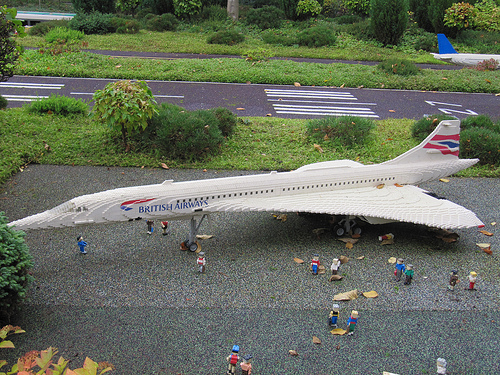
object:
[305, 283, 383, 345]
lego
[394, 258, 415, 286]
spectators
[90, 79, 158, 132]
leaves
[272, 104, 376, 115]
lines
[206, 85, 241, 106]
asphalt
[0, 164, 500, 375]
tarmac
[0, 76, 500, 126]
runway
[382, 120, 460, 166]
tail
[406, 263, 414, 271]
head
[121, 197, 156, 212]
logo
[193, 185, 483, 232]
wing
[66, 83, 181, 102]
line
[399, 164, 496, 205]
windows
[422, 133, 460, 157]
logo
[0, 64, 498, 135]
road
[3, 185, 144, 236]
plane front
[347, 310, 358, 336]
model spectator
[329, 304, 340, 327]
model spectator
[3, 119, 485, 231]
airplane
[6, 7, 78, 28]
building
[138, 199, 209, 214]
british airways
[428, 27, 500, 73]
tail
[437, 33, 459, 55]
tail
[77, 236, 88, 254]
figurine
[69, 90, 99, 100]
white line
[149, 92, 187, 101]
white line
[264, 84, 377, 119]
lines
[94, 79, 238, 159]
bushes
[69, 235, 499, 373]
people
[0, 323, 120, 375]
leaves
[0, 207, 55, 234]
nose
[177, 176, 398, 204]
small windows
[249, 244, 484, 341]
figures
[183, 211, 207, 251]
landing gear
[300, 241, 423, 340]
people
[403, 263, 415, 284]
person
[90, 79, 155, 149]
bush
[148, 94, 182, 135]
bush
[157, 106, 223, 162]
bush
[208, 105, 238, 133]
bush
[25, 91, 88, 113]
bush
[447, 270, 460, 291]
people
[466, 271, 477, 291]
people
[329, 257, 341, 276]
people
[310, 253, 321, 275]
people